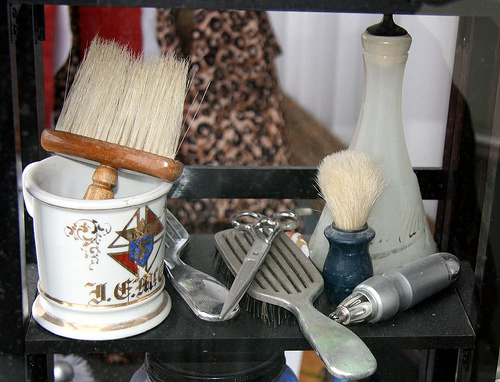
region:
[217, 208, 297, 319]
scissors on shelf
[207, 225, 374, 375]
hair brush on shelf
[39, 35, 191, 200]
brush in shaving cup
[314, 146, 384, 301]
blue shaving cream brush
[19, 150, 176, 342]
shaving cup on shelf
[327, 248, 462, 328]
nose hair trimmer on shelf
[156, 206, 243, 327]
silver hair brush on shelf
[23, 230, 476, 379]
black shelf with shaving supplies on it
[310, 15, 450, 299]
glass bottle on shelf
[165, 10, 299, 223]
leopard fabric draped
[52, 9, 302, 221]
cheetah print cloth behind brush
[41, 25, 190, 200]
long brush in cup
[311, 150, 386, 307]
blue handle shaving cream brush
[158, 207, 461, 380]
metal barber tools on shelf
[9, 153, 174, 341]
the cup is white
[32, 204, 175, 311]
cup has gold, red, and blue design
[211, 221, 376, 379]
hair brush under scissors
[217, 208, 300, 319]
metal scissors on brush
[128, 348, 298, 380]
large blue jug with black lid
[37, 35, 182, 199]
wooden handle on horse hair brush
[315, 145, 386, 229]
Clean shaving cream brush bristles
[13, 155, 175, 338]
Ceramic mug on shelf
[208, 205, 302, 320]
Metal scissors on shelf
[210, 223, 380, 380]
Hair brush on shelf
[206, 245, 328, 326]
Soft bristles of hair brush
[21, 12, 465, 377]
Men's hair care items on shelf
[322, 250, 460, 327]
Electric nostril hair clipper on shelf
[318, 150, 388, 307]
Shaving cream applicator brush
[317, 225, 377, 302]
Blue handle on shaving brush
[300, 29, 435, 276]
White bottle on shelf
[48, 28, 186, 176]
brush with wood handle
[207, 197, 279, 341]
silver scissors for cutting hair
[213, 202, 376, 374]
brush with silver handle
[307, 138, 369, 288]
brush with blue handle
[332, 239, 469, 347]
silver nose hair trimmer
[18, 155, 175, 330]
white cup with gold writing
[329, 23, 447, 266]
white glass har with black top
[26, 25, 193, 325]
cup with brush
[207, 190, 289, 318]
scissors on top brush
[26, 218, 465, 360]
small black table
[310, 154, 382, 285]
brush on the table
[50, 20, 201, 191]
brush on the table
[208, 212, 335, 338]
brush on the table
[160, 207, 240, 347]
Fork on the table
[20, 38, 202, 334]
brush in a cup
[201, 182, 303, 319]
scissor on top of the brush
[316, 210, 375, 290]
brush with a blue handle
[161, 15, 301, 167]
cheetah cloth in the mirror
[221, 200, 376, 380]
metal brush with scissors on top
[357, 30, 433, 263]
lamp on the table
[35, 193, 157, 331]
mug on the table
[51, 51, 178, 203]
brush in the mug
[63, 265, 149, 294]
writing on the mug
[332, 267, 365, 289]
the vase is blue